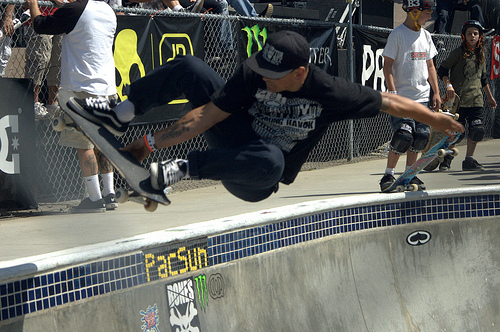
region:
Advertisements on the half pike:
[133, 240, 234, 330]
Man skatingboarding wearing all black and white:
[56, 3, 466, 205]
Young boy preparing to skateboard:
[377, 2, 462, 198]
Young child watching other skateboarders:
[434, 9, 499, 173]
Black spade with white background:
[399, 223, 436, 253]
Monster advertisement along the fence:
[234, 19, 344, 93]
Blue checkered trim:
[3, 195, 498, 318]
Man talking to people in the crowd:
[54, 1, 136, 212]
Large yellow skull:
[99, 23, 161, 129]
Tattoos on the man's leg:
[73, 148, 119, 178]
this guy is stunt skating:
[15, 7, 497, 221]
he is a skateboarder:
[38, 33, 471, 205]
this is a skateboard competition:
[39, 21, 481, 219]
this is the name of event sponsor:
[130, 225, 227, 296]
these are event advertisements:
[230, 13, 407, 103]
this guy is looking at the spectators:
[22, 1, 127, 214]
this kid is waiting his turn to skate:
[388, 0, 469, 199]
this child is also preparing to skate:
[440, 18, 492, 173]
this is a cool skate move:
[70, 33, 465, 225]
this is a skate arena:
[31, 190, 480, 330]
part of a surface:
[335, 237, 402, 291]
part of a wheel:
[373, 158, 417, 203]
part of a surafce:
[282, 247, 334, 290]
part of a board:
[388, 142, 422, 179]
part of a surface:
[251, 236, 303, 286]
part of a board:
[408, 147, 428, 162]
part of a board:
[403, 154, 421, 172]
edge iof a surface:
[230, 210, 265, 226]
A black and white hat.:
[246, 32, 310, 80]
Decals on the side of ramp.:
[137, 247, 227, 328]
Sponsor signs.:
[96, 17, 498, 109]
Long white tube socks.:
[81, 171, 118, 196]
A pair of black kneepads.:
[392, 122, 432, 162]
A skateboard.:
[51, 91, 169, 216]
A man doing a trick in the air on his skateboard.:
[51, 32, 466, 254]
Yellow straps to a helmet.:
[410, 7, 425, 29]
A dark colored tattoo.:
[156, 114, 203, 143]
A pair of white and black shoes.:
[68, 93, 190, 185]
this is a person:
[58, 23, 472, 205]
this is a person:
[33, 3, 132, 208]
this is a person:
[372, 0, 447, 199]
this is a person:
[437, 3, 495, 182]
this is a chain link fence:
[3, 0, 486, 207]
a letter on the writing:
[124, 251, 157, 290]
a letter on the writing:
[149, 248, 174, 284]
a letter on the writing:
[163, 248, 184, 277]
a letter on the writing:
[177, 248, 189, 274]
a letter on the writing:
[186, 248, 201, 272]